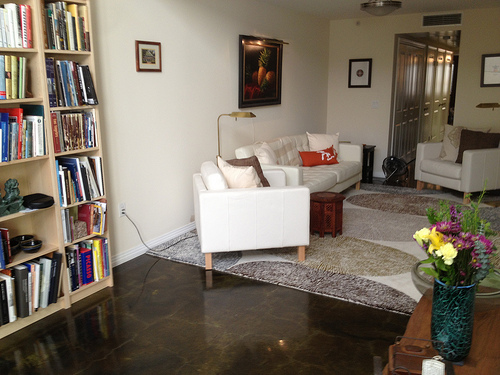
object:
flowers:
[412, 179, 497, 287]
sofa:
[234, 131, 362, 194]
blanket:
[268, 134, 308, 166]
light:
[242, 39, 266, 48]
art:
[238, 34, 283, 109]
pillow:
[218, 156, 264, 189]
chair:
[191, 174, 311, 271]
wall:
[92, 0, 328, 269]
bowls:
[20, 239, 43, 253]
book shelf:
[0, 0, 113, 338]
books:
[0, 3, 33, 49]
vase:
[429, 276, 478, 365]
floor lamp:
[216, 111, 256, 168]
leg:
[205, 253, 212, 270]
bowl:
[411, 258, 500, 300]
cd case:
[22, 193, 55, 210]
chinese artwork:
[0, 178, 26, 217]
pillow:
[296, 144, 339, 167]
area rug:
[145, 182, 500, 317]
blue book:
[2, 113, 9, 161]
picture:
[135, 40, 162, 72]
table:
[383, 290, 500, 374]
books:
[41, 1, 90, 51]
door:
[392, 38, 428, 165]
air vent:
[422, 13, 461, 26]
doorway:
[387, 30, 461, 181]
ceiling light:
[360, 1, 402, 16]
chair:
[414, 124, 500, 204]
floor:
[0, 253, 413, 374]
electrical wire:
[122, 212, 199, 252]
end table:
[310, 191, 346, 238]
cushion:
[200, 160, 228, 191]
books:
[0, 55, 26, 100]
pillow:
[455, 129, 499, 165]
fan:
[382, 156, 408, 186]